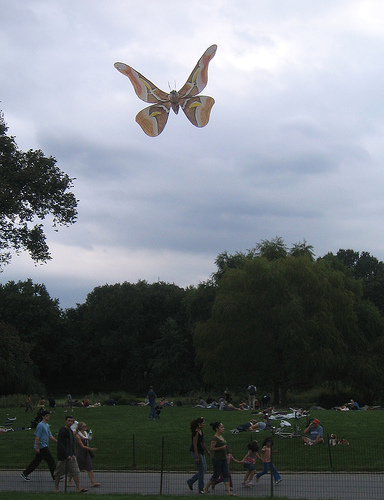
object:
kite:
[113, 42, 216, 137]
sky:
[217, 1, 383, 238]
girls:
[261, 437, 283, 479]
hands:
[239, 460, 245, 465]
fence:
[96, 439, 317, 499]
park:
[0, 2, 383, 499]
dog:
[326, 433, 351, 448]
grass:
[351, 412, 383, 472]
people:
[247, 383, 257, 411]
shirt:
[33, 420, 53, 449]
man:
[21, 410, 55, 481]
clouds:
[82, 147, 339, 234]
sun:
[218, 2, 383, 108]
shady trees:
[195, 256, 350, 405]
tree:
[1, 108, 80, 268]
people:
[230, 414, 269, 435]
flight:
[4, 1, 383, 249]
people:
[201, 420, 237, 500]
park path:
[278, 471, 383, 500]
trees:
[0, 275, 59, 397]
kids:
[240, 441, 259, 488]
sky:
[78, 138, 383, 246]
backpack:
[250, 386, 255, 395]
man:
[301, 419, 324, 446]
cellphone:
[311, 420, 315, 425]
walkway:
[0, 471, 381, 500]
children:
[223, 438, 281, 494]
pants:
[21, 449, 56, 482]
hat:
[312, 418, 319, 426]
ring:
[78, 431, 90, 442]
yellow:
[188, 102, 200, 110]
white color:
[143, 109, 158, 135]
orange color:
[124, 69, 143, 96]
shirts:
[260, 446, 272, 464]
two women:
[187, 418, 210, 496]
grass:
[96, 414, 190, 470]